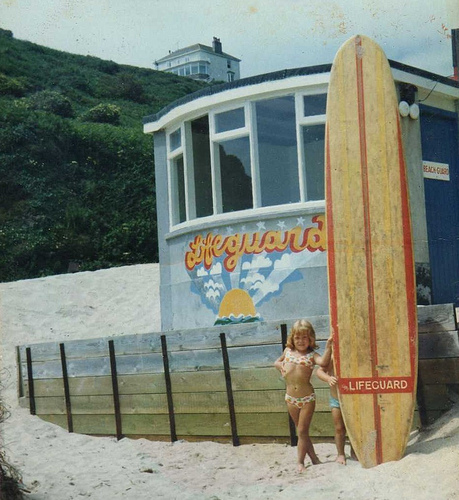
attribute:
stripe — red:
[317, 137, 352, 396]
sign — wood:
[163, 214, 329, 374]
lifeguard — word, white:
[184, 214, 327, 270]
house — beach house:
[139, 60, 457, 329]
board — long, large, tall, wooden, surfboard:
[324, 36, 419, 474]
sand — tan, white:
[2, 411, 457, 499]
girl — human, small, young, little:
[275, 320, 333, 469]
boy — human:
[313, 334, 357, 464]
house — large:
[154, 36, 241, 87]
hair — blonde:
[287, 321, 316, 355]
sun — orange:
[217, 292, 257, 317]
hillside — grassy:
[0, 40, 205, 283]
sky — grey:
[240, 0, 458, 77]